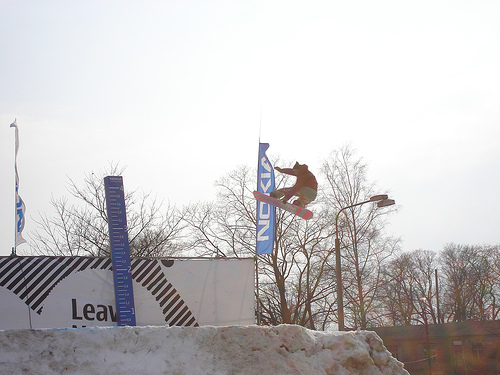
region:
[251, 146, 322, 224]
person doing tricks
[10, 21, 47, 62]
white clouds in blue sky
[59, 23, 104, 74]
white clouds in blue sky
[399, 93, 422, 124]
white clouds in blue sky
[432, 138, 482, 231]
white clouds in blue sky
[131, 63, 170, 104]
white clouds in blue sky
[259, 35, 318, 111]
white clouds in blue sky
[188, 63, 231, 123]
white clouds in blue sky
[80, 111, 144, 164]
white clouds in blue sky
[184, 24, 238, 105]
white clouds in blue sky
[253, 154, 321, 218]
snowboarder in a jump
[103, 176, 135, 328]
a blue measuring device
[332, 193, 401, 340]
overhead lighting with two lamps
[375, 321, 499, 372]
a building with an awning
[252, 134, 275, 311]
blue banner of a sponser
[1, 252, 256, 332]
black and white tarp mounted to a fence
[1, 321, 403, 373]
packed snow for snow boarding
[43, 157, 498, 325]
trees without leaves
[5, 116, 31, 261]
banner mounted to a street light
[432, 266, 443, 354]
a utility pole nearer the building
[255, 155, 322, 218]
man doing tricks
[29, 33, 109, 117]
white clouds in blue sky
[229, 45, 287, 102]
white clouds in blue sky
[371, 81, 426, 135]
white clouds in blue sky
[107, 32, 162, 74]
white clouds in blue sky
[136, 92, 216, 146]
white clouds in blue sky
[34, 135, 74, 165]
white clouds in blue sky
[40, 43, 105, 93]
white clouds in blue sky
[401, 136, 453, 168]
white clouds in blue sky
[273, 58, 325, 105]
white clouds in blue sky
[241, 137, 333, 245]
person is on snowboard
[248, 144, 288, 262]
blue and white banner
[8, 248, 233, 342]
black and white ad board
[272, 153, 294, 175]
person wears black cap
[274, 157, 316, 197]
person wears orange jacket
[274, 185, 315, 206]
person wears grey pants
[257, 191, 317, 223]
red and grey board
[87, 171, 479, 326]
bare trees behind boarder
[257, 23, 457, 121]
sky is grey and cloudy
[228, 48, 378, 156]
thick clouds in sky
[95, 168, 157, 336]
the ruler is blue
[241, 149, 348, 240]
player with the snowboard